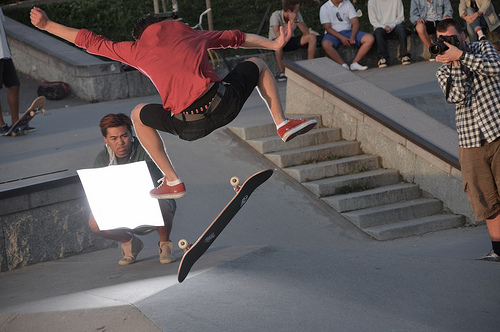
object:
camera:
[427, 34, 456, 55]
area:
[1, 0, 496, 332]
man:
[320, 0, 375, 71]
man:
[266, 1, 314, 82]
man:
[366, 0, 411, 67]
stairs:
[227, 112, 464, 239]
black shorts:
[139, 60, 258, 139]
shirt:
[78, 145, 176, 219]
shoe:
[276, 117, 315, 141]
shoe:
[149, 178, 186, 200]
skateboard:
[175, 167, 273, 282]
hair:
[98, 113, 133, 135]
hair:
[433, 17, 461, 30]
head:
[96, 114, 134, 157]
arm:
[39, 22, 129, 62]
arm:
[203, 29, 275, 49]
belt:
[175, 83, 224, 121]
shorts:
[137, 60, 259, 144]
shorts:
[268, 30, 304, 52]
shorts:
[323, 30, 367, 48]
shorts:
[414, 16, 440, 37]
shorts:
[1, 55, 21, 88]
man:
[411, 14, 496, 260]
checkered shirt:
[432, 40, 499, 148]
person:
[26, 4, 323, 198]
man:
[85, 113, 173, 264]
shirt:
[73, 18, 237, 110]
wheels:
[227, 177, 237, 185]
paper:
[72, 160, 164, 229]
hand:
[433, 39, 462, 62]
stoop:
[274, 24, 494, 55]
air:
[0, 0, 495, 133]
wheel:
[177, 238, 188, 248]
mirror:
[74, 160, 164, 230]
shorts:
[456, 144, 498, 219]